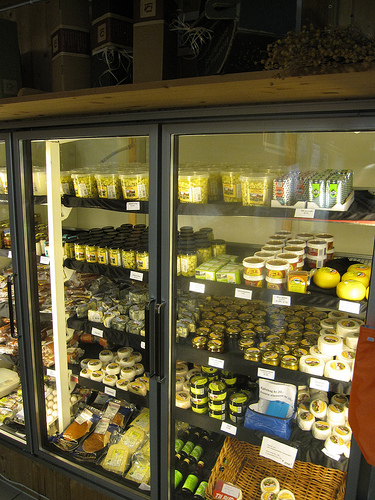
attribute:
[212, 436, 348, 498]
basket — wicker, brown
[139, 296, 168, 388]
handles — black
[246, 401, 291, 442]
pouch — blue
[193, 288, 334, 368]
jars — glass, small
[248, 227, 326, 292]
container — clear, plastic, small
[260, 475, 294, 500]
items — small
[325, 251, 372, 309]
cheese — yellow, white, cold, displayed, for sale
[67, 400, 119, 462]
sandwiches — ready-made, displayed, cold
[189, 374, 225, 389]
lids — black, yellow, gold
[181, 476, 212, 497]
labels — green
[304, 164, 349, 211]
boxes — green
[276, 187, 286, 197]
labels — orange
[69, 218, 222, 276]
bottles — clear, small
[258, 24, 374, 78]
flowers — small